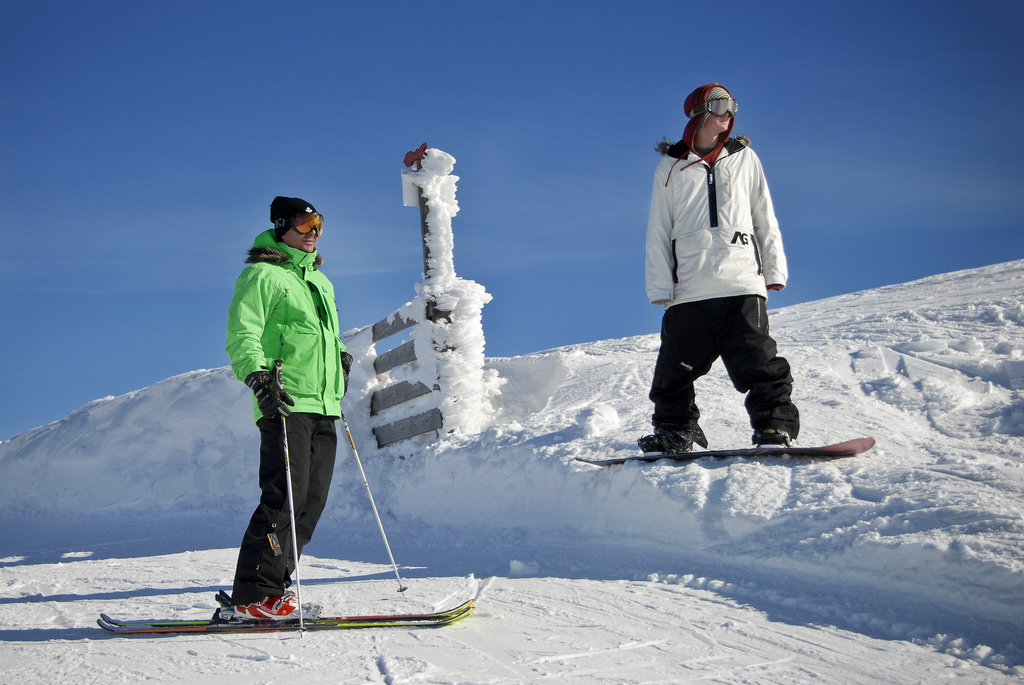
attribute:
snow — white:
[0, 144, 1022, 680]